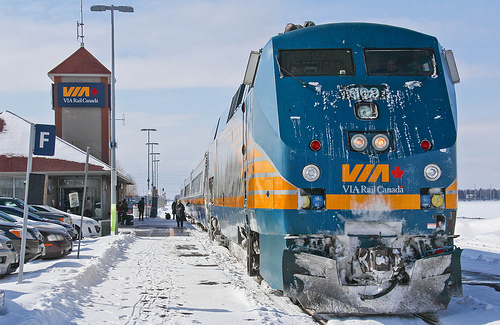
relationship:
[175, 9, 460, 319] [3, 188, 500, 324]
train in snow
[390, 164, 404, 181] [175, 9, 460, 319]
leaf on train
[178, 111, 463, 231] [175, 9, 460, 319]
lines on train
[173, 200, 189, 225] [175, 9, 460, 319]
person next to train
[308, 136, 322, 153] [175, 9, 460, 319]
light on train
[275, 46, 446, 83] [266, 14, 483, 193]
windows on front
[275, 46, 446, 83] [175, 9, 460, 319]
windows on train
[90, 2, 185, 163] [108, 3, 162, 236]
lights on poles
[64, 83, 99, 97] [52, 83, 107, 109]
logo on sign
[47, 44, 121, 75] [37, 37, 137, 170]
roof ion tower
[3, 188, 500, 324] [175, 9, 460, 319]
snow on train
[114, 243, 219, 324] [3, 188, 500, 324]
track in snow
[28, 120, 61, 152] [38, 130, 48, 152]
sign has letter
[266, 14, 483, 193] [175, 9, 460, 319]
front on train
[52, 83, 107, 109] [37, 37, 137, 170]
sign on tower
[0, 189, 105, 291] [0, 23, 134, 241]
cars at station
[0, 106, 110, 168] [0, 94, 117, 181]
snow on roof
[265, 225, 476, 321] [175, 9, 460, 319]
catcher on train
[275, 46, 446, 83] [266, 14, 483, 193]
windows of front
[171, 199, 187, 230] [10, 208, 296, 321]
person walking in snow